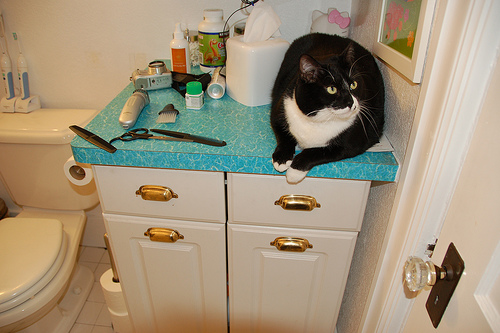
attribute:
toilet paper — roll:
[56, 140, 98, 186]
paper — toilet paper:
[97, 245, 134, 329]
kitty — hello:
[298, 8, 354, 37]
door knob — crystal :
[395, 255, 445, 302]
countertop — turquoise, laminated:
[129, 133, 180, 165]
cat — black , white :
[273, 51, 384, 162]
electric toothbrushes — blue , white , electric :
[0, 28, 40, 113]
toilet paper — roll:
[86, 265, 153, 331]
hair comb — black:
[66, 120, 124, 166]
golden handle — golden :
[275, 192, 317, 214]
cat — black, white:
[266, 33, 386, 185]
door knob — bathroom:
[404, 257, 444, 297]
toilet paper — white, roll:
[65, 150, 94, 187]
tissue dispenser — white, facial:
[228, 32, 290, 111]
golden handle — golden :
[141, 224, 190, 249]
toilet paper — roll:
[61, 154, 90, 196]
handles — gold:
[82, 181, 203, 228]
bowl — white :
[1, 221, 66, 321]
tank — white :
[0, 113, 96, 211]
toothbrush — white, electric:
[2, 30, 39, 115]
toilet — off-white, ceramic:
[1, 104, 112, 328]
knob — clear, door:
[400, 255, 452, 294]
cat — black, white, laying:
[271, 16, 455, 190]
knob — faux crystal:
[403, 259, 434, 294]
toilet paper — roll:
[62, 152, 95, 196]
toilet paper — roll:
[94, 269, 132, 311]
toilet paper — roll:
[103, 309, 136, 331]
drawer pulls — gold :
[252, 182, 349, 222]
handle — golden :
[134, 181, 181, 208]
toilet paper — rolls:
[101, 268, 127, 310]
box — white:
[224, 30, 289, 108]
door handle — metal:
[389, 242, 478, 323]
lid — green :
[180, 76, 211, 97]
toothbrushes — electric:
[2, 28, 41, 118]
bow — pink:
[323, 6, 356, 31]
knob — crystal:
[393, 250, 434, 306]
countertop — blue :
[64, 54, 396, 184]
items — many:
[61, 25, 233, 155]